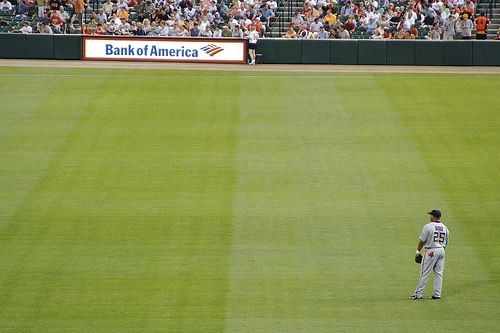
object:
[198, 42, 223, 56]
logo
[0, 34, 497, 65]
fence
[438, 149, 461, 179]
ground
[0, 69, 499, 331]
game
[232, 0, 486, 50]
crowd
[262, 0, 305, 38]
stairs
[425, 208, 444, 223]
head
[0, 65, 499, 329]
baseball field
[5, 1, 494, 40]
crowd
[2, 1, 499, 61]
stadium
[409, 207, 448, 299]
baaseball player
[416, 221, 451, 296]
grey uniform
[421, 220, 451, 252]
jersey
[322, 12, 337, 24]
yellow shirt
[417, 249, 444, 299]
pants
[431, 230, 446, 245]
number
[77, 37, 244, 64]
advertisement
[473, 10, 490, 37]
fan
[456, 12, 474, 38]
fan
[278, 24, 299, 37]
fan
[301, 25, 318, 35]
fan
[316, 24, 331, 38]
fan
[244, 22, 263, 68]
person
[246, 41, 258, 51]
shorts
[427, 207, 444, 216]
hat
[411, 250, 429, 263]
catchers mit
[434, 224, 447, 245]
writting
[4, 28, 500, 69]
wall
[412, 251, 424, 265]
glove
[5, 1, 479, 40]
stands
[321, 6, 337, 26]
person